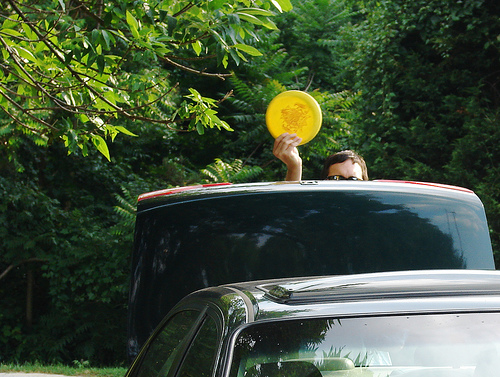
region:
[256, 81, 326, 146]
PLASTIC YELLOW FRISBEE IN HAND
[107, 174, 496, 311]
RAISED BLACK TRUNK OF CAR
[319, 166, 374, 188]
SUNGLASSES ON MAN WITH FRISBEE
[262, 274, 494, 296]
SUNROOF OF BLACK CAR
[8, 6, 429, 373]
TALL GREEN FERN TREES IN BACKGROUND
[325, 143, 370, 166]
SHORT BROWN HAIR OF MAN WITH FRISBEE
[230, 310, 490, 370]
FRONT WINDSHIELD OF CAR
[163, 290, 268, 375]
SIDE WINDOWS OF BLACK CAR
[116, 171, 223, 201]
RED TAIL LIGHTS ON OPEN TRUNK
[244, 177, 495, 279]
REFLECTION OF TREE ON TRUNK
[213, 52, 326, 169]
The person is holding a frisbee.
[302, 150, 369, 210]
The person head is sticking out of the roof of the car.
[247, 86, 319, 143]
The frisbee is yellow.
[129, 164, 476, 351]
Two cars driving down the road.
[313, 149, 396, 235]
A person inside the car.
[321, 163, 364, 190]
The person is wearing glasses.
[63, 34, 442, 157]
The trees are green.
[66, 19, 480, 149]
Trees behind the car.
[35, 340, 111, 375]
The grass is green.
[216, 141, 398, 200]
The car has a sunroof.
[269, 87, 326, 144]
yellow plastic frisbee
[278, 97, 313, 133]
design on top of frisbee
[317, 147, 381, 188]
man in black sun glasses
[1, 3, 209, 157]
tree covered in light green leaves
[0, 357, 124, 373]
grass growing beside road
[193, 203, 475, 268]
reflection of trees on car trunk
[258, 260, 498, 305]
sun roof on top of black car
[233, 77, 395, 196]
man holding a yellow frisbee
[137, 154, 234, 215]
red tail light on car trunk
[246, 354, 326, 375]
black car seat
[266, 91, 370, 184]
a man holding a frisbee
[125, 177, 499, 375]
a car with an open trunk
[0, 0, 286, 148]
branches with green leaves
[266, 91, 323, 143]
a yellow frisbee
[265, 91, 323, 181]
a man's hand holding a frisbee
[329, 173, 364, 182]
sunglasses on a man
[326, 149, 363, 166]
a man's hair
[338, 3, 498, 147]
lush green foliage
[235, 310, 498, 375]
the windshield on a car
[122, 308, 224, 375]
passenger windows on a car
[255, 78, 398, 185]
a person holding a yellow frisbee.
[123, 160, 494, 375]
a vehicle with a person on it.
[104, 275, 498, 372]
a car driving in front of a van.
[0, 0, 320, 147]
a lush green tree.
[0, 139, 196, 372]
A forest of green leaves.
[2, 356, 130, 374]
A field of green grass.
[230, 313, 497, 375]
a windshield on a car.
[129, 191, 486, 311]
a shiny wind shield.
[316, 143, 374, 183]
a man with a head of hair.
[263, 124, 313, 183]
a hand holding a yellow frisbee.